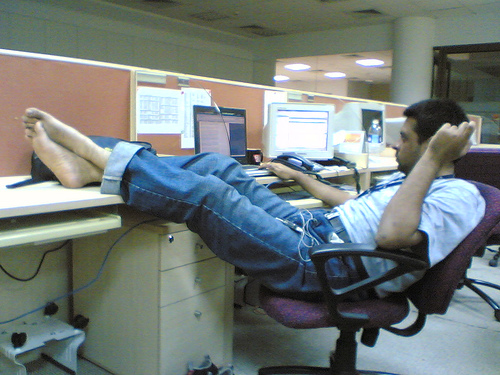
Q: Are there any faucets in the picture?
A: No, there are no faucets.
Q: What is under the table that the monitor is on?
A: The drawer is under the table.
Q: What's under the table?
A: The drawer is under the table.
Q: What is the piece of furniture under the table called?
A: The piece of furniture is a drawer.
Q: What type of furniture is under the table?
A: The piece of furniture is a drawer.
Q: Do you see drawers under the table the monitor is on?
A: Yes, there is a drawer under the table.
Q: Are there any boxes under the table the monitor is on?
A: No, there is a drawer under the table.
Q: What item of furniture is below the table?
A: The piece of furniture is a drawer.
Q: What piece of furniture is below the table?
A: The piece of furniture is a drawer.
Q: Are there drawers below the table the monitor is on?
A: Yes, there is a drawer below the table.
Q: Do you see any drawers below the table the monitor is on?
A: Yes, there is a drawer below the table.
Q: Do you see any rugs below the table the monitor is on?
A: No, there is a drawer below the table.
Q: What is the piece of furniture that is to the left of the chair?
A: The piece of furniture is a drawer.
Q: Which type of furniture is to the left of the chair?
A: The piece of furniture is a drawer.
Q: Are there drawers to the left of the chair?
A: Yes, there is a drawer to the left of the chair.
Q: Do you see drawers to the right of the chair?
A: No, the drawer is to the left of the chair.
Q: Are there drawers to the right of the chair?
A: No, the drawer is to the left of the chair.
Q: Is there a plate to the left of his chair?
A: No, there is a drawer to the left of the chair.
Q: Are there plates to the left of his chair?
A: No, there is a drawer to the left of the chair.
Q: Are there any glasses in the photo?
A: No, there are no glasses.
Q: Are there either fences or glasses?
A: No, there are no glasses or fences.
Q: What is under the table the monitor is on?
A: The drawer is under the table.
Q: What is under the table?
A: The drawer is under the table.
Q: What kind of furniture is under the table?
A: The piece of furniture is a drawer.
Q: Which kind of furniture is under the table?
A: The piece of furniture is a drawer.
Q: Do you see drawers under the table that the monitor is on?
A: Yes, there is a drawer under the table.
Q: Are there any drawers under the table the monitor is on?
A: Yes, there is a drawer under the table.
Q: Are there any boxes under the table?
A: No, there is a drawer under the table.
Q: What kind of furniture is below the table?
A: The piece of furniture is a drawer.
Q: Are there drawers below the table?
A: Yes, there is a drawer below the table.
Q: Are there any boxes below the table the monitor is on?
A: No, there is a drawer below the table.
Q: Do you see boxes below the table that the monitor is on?
A: No, there is a drawer below the table.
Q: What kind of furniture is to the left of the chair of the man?
A: The piece of furniture is a drawer.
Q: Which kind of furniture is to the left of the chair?
A: The piece of furniture is a drawer.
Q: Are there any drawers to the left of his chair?
A: Yes, there is a drawer to the left of the chair.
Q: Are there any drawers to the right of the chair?
A: No, the drawer is to the left of the chair.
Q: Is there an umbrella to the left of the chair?
A: No, there is a drawer to the left of the chair.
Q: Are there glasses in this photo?
A: No, there are no glasses.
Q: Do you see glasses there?
A: No, there are no glasses.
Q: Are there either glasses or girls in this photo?
A: No, there are no glasses or girls.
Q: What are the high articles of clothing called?
A: The clothing items are jeans.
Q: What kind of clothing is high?
A: The clothing is jeans.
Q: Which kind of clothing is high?
A: The clothing is jeans.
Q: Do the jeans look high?
A: Yes, the jeans are high.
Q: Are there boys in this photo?
A: No, there are no boys.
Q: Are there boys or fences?
A: No, there are no boys or fences.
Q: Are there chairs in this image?
A: Yes, there is a chair.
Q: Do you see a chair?
A: Yes, there is a chair.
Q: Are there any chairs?
A: Yes, there is a chair.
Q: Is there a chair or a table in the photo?
A: Yes, there is a chair.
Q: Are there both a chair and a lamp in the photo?
A: No, there is a chair but no lamps.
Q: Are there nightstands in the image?
A: No, there are no nightstands.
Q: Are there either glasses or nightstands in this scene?
A: No, there are no nightstands or glasses.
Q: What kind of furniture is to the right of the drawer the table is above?
A: The piece of furniture is a chair.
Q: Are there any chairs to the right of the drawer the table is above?
A: Yes, there is a chair to the right of the drawer.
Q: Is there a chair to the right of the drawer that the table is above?
A: Yes, there is a chair to the right of the drawer.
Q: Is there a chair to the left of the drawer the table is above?
A: No, the chair is to the right of the drawer.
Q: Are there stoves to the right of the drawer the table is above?
A: No, there is a chair to the right of the drawer.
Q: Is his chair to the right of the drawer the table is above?
A: Yes, the chair is to the right of the drawer.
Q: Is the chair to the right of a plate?
A: No, the chair is to the right of the drawer.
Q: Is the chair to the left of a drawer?
A: No, the chair is to the right of a drawer.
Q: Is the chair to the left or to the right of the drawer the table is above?
A: The chair is to the right of the drawer.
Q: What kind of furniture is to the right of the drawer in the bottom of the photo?
A: The piece of furniture is a chair.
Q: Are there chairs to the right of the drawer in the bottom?
A: Yes, there is a chair to the right of the drawer.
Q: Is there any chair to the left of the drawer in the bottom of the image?
A: No, the chair is to the right of the drawer.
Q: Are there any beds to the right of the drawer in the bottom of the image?
A: No, there is a chair to the right of the drawer.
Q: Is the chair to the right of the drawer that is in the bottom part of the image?
A: Yes, the chair is to the right of the drawer.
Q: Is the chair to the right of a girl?
A: No, the chair is to the right of the drawer.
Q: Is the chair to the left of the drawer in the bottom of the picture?
A: No, the chair is to the right of the drawer.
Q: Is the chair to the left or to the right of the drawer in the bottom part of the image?
A: The chair is to the right of the drawer.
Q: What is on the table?
A: The monitor is on the table.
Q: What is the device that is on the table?
A: The device is a monitor.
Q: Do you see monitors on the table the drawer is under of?
A: Yes, there is a monitor on the table.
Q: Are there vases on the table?
A: No, there is a monitor on the table.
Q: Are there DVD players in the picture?
A: No, there are no DVD players.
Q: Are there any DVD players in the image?
A: No, there are no DVD players.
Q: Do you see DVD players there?
A: No, there are no DVD players.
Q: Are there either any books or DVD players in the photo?
A: No, there are no DVD players or books.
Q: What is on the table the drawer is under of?
A: The monitor is on the table.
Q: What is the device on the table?
A: The device is a monitor.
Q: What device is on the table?
A: The device is a monitor.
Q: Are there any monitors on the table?
A: Yes, there is a monitor on the table.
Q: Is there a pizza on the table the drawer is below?
A: No, there is a monitor on the table.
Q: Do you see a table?
A: Yes, there is a table.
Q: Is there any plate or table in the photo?
A: Yes, there is a table.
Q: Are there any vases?
A: No, there are no vases.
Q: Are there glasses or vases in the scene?
A: No, there are no vases or glasses.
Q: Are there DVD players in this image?
A: No, there are no DVD players.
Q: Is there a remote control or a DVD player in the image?
A: No, there are no DVD players or remote controls.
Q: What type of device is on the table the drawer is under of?
A: The device is a monitor.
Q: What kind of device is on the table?
A: The device is a monitor.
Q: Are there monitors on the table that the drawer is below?
A: Yes, there is a monitor on the table.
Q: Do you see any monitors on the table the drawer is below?
A: Yes, there is a monitor on the table.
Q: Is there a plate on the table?
A: No, there is a monitor on the table.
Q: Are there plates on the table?
A: No, there is a monitor on the table.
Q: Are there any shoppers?
A: No, there are no shoppers.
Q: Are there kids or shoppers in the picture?
A: No, there are no shoppers or kids.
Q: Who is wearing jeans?
A: The man is wearing jeans.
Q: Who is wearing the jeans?
A: The man is wearing jeans.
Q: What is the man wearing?
A: The man is wearing jeans.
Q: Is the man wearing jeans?
A: Yes, the man is wearing jeans.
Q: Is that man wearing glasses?
A: No, the man is wearing jeans.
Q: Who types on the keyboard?
A: The man types on the keyboard.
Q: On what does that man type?
A: The man types on the keyboard.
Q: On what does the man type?
A: The man types on the keyboard.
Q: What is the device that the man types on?
A: The device is a keyboard.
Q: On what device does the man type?
A: The man types on the keyboard.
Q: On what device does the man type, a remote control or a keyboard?
A: The man types on a keyboard.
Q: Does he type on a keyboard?
A: Yes, the man types on a keyboard.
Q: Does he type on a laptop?
A: No, the man types on a keyboard.